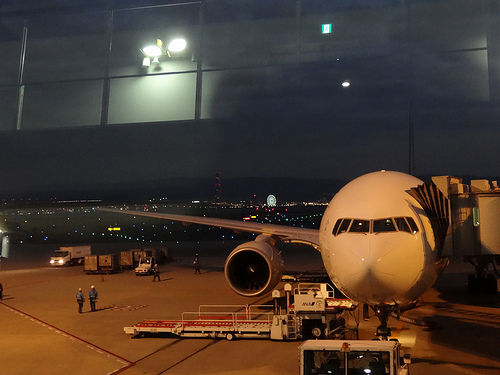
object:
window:
[369, 216, 398, 234]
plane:
[95, 169, 499, 344]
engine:
[221, 240, 284, 298]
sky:
[0, 119, 499, 195]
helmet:
[89, 285, 95, 289]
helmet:
[77, 287, 84, 292]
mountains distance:
[0, 175, 347, 206]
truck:
[46, 243, 98, 267]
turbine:
[225, 250, 271, 294]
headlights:
[166, 36, 188, 55]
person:
[87, 284, 100, 313]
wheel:
[388, 336, 398, 342]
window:
[100, 67, 207, 127]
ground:
[0, 254, 499, 374]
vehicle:
[296, 338, 411, 374]